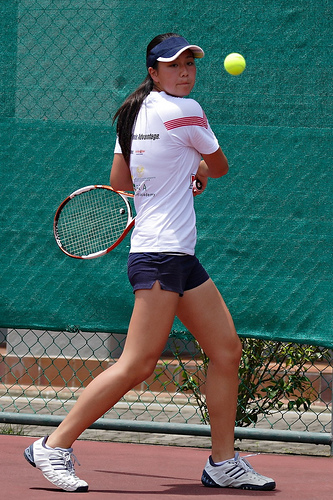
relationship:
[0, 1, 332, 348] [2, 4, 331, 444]
cover over fence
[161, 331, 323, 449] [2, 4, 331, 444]
plant near fence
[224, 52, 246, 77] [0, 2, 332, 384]
tennis ball in air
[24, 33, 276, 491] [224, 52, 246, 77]
woman swinging at tennis ball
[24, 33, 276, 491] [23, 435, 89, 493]
woman wearing a shoe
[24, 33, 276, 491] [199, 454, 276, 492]
woman wearing a shoe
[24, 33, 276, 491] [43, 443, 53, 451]
woman wearing a sock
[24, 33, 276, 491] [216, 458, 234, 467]
woman wearing a sock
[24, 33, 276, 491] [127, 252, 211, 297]
woman wearing shorts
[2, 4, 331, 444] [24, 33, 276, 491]
fence behind woman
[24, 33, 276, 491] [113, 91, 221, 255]
woman wearing a tee shirt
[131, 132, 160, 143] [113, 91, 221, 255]
words on back of tee shirt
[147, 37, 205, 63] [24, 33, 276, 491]
visor on woman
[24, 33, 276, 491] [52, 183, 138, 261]
woman holding racket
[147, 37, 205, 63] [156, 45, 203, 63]
visor trimmed white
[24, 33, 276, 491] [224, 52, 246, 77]
woman preparing to hit tennis ball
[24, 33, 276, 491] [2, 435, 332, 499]
woman on a ten court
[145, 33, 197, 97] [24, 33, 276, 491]
head of a woman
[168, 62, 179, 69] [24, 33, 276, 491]
eye of woman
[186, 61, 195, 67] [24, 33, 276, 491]
eye of woman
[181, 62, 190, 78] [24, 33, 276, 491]
nose of woman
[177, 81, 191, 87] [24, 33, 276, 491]
mouth of woman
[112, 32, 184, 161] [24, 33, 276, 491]
hair of woman